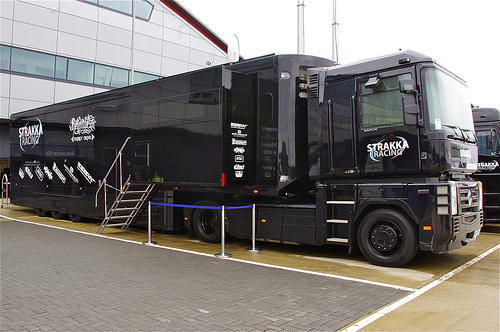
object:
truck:
[465, 103, 499, 226]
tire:
[68, 214, 80, 222]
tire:
[51, 210, 61, 218]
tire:
[36, 209, 46, 217]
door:
[351, 65, 421, 174]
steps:
[324, 183, 356, 249]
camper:
[8, 49, 485, 268]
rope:
[150, 202, 254, 210]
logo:
[367, 136, 410, 162]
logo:
[18, 117, 45, 152]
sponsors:
[16, 112, 98, 184]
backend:
[7, 90, 126, 223]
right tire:
[356, 209, 420, 268]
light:
[422, 226, 431, 231]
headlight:
[450, 181, 459, 217]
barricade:
[141, 201, 263, 259]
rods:
[147, 201, 256, 257]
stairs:
[94, 136, 156, 234]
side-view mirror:
[399, 84, 420, 127]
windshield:
[418, 69, 476, 134]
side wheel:
[191, 200, 228, 243]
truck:
[6, 49, 483, 268]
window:
[9, 45, 56, 78]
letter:
[366, 136, 410, 162]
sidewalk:
[0, 215, 416, 331]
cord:
[150, 202, 222, 210]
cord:
[222, 205, 252, 210]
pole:
[148, 201, 152, 243]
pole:
[221, 205, 226, 257]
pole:
[252, 204, 255, 250]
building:
[0, 0, 246, 169]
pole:
[295, 0, 305, 56]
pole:
[331, 0, 339, 64]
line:
[332, 259, 483, 329]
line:
[0, 213, 413, 293]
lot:
[2, 200, 483, 329]